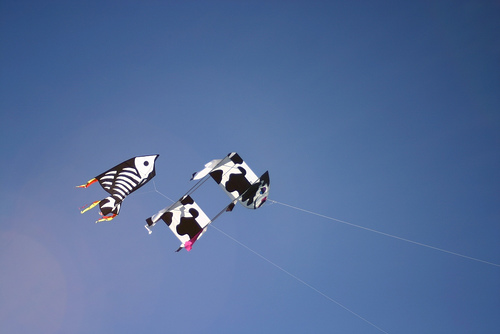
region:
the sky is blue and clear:
[22, 8, 477, 131]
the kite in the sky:
[62, 148, 171, 230]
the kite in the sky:
[148, 153, 276, 256]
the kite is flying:
[64, 143, 176, 233]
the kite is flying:
[142, 151, 279, 261]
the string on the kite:
[125, 176, 398, 331]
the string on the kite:
[267, 185, 497, 280]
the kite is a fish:
[72, 148, 165, 230]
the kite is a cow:
[140, 153, 285, 258]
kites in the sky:
[53, 102, 368, 292]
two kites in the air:
[47, 95, 332, 282]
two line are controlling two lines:
[92, 142, 472, 319]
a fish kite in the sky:
[62, 126, 161, 218]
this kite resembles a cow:
[139, 159, 288, 259]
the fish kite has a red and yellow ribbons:
[65, 145, 152, 215]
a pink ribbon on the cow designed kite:
[175, 223, 204, 260]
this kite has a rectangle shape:
[137, 150, 285, 265]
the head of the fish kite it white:
[121, 144, 171, 184]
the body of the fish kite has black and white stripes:
[91, 162, 143, 209]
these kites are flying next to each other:
[52, 135, 292, 247]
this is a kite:
[62, 121, 162, 222]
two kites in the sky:
[68, 107, 270, 258]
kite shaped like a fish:
[58, 142, 156, 237]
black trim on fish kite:
[71, 145, 165, 224]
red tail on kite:
[74, 168, 101, 196]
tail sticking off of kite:
[71, 171, 116, 223]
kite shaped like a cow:
[145, 131, 277, 251]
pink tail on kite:
[175, 225, 206, 260]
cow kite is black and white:
[153, 145, 277, 273]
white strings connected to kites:
[208, 182, 480, 324]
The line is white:
[102, 166, 118, 176]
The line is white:
[98, 171, 115, 181]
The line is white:
[102, 177, 114, 187]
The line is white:
[98, 183, 111, 195]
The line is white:
[121, 162, 140, 174]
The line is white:
[118, 169, 140, 184]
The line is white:
[114, 173, 136, 186]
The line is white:
[116, 178, 128, 190]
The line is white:
[111, 183, 128, 200]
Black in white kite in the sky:
[73, 123, 290, 254]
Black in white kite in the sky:
[134, 178, 231, 256]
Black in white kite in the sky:
[188, 145, 298, 230]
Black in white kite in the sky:
[43, 133, 170, 239]